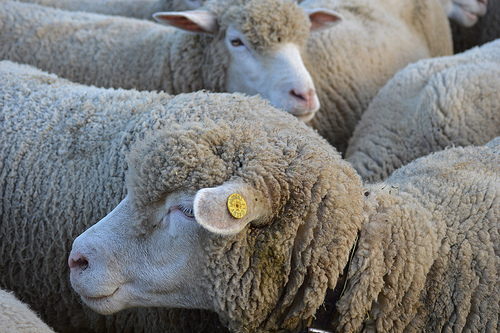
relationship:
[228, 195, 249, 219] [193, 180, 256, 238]
tag in ear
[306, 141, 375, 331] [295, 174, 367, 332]
neck has folds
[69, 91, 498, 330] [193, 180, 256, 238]
lamb has ear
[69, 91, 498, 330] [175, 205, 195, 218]
lamb has eyes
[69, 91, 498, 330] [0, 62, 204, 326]
lamb has wool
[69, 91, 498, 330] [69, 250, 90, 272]
lamb has nose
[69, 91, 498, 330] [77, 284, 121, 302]
lamb has mouth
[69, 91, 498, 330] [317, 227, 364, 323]
lamb has collar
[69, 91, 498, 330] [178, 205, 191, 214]
lamb has eyelash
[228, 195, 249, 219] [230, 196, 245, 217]
tag has writing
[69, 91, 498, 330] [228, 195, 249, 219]
lamb has tag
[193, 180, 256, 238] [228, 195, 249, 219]
ear has tag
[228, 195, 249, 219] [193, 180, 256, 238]
tag on ear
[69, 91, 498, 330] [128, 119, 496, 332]
lamb has fur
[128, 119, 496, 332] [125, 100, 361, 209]
fur on head